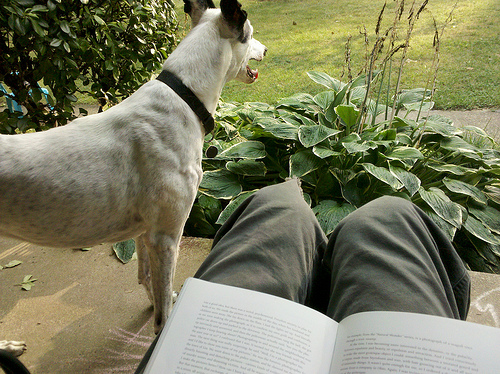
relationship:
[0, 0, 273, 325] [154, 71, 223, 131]
dog wears collar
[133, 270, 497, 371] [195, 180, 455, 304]
book on lap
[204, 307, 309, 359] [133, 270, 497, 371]
text in book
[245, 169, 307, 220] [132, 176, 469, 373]
knee of person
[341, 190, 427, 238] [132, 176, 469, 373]
knee of person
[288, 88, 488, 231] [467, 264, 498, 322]
plant beside porch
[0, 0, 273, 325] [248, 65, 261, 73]
dog has teeth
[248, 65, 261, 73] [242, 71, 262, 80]
teeth in mouth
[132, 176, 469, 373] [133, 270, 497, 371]
person has book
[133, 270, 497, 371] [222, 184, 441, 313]
book on lap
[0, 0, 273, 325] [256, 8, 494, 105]
dog near yard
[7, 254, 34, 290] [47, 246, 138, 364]
leaves on ground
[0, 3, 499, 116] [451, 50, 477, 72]
lawn  green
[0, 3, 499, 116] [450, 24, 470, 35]
lawn  brown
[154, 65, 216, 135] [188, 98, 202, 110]
collar  black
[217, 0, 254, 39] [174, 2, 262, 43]
ear  upwards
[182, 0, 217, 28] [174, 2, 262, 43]
ear  upwards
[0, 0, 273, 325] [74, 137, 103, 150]
dog  white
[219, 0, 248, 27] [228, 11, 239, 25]
ear  brown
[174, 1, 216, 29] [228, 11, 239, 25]
ear  brown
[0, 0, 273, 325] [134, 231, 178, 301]
dog has leg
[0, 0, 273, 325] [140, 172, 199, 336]
dog has leg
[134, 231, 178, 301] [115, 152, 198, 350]
leg in front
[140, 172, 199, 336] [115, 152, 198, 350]
leg in front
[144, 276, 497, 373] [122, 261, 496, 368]
book  open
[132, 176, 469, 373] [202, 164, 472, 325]
person has lap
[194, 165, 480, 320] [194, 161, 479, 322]
person has pants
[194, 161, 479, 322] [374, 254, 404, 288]
pants are gray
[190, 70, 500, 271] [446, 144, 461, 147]
plant are green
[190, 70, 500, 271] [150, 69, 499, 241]
plant on ground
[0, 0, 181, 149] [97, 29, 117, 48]
shrubbery  green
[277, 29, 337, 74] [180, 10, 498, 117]
shadow on grass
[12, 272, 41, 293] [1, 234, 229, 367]
leaf on ground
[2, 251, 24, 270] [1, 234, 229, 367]
leaf on ground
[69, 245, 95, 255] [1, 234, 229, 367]
leaf on ground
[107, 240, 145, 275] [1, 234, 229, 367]
leaf on ground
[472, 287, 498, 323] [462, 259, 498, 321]
mark on ground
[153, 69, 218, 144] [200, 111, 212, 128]
collar  black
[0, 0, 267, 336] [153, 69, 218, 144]
dog has collar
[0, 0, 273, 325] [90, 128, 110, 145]
dog has white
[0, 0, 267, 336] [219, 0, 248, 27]
dog has ear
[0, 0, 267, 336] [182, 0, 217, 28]
dog has ear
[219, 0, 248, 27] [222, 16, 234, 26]
ear  brown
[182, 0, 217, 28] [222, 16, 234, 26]
ear  brown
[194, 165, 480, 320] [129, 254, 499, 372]
person has book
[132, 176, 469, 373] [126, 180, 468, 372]
person has pants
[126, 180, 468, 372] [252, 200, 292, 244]
pants are green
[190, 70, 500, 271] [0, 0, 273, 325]
plant by dog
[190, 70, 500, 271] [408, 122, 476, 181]
plant  leafy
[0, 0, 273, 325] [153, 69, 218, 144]
dog has collar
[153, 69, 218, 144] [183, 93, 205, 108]
collar  black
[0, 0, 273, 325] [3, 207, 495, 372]
dog on concrete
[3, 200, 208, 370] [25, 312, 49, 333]
concrete  tan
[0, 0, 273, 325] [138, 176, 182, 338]
dog has leg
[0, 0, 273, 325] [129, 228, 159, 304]
dog has leg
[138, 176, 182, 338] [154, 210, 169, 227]
leg  white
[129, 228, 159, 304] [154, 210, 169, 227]
leg  white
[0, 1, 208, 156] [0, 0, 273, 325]
bush front of dog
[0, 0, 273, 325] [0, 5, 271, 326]
dog  up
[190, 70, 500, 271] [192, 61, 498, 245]
plant  large